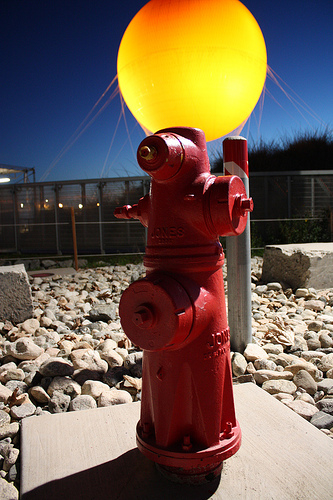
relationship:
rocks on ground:
[15, 329, 130, 399] [2, 301, 163, 420]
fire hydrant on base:
[111, 125, 253, 487] [12, 379, 331, 498]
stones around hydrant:
[244, 357, 299, 404] [115, 112, 247, 463]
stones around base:
[244, 357, 299, 404] [22, 386, 330, 479]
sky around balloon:
[2, 0, 114, 161] [116, 0, 266, 142]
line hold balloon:
[119, 95, 141, 174] [116, 0, 266, 142]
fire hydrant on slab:
[111, 125, 253, 487] [22, 415, 160, 498]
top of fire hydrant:
[136, 125, 211, 179] [111, 125, 253, 487]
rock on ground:
[245, 342, 267, 362] [0, 258, 330, 496]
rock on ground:
[306, 335, 319, 350] [0, 258, 330, 496]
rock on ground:
[296, 286, 306, 296] [0, 258, 330, 496]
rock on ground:
[265, 281, 283, 289] [0, 258, 330, 496]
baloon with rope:
[115, 0, 269, 141] [264, 65, 313, 134]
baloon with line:
[115, 0, 269, 141] [119, 95, 141, 174]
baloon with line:
[115, 0, 269, 141] [37, 72, 120, 182]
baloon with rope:
[115, 0, 269, 141] [242, 115, 252, 153]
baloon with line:
[115, 0, 269, 141] [99, 103, 125, 175]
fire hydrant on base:
[111, 125, 245, 489] [18, 384, 333, 499]